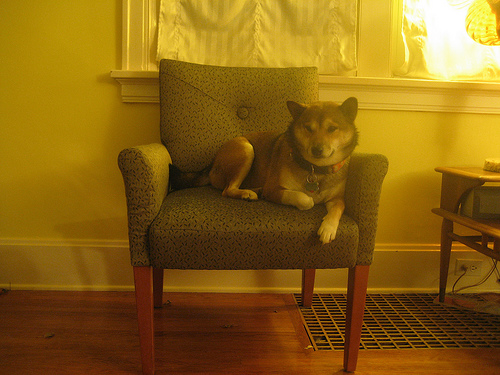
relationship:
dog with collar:
[210, 96, 360, 245] [290, 143, 350, 193]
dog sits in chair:
[199, 91, 363, 245] [118, 57, 394, 372]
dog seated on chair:
[210, 96, 360, 245] [118, 57, 394, 372]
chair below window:
[118, 57, 394, 372] [151, 1, 361, 81]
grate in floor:
[291, 293, 500, 353] [7, 286, 497, 372]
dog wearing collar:
[210, 96, 360, 245] [283, 127, 355, 177]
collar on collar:
[289, 144, 345, 193] [283, 127, 355, 177]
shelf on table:
[429, 198, 498, 248] [426, 157, 497, 323]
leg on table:
[433, 219, 457, 301] [426, 157, 497, 323]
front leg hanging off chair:
[317, 216, 341, 247] [118, 57, 394, 372]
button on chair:
[230, 98, 255, 119] [118, 57, 394, 372]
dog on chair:
[210, 96, 360, 245] [118, 57, 394, 372]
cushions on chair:
[141, 179, 372, 289] [118, 57, 394, 372]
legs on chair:
[126, 267, 162, 373] [118, 57, 394, 372]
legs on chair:
[301, 266, 317, 313] [118, 57, 394, 372]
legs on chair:
[339, 260, 372, 372] [118, 57, 394, 372]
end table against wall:
[430, 166, 500, 303] [0, 1, 500, 294]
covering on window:
[153, 0, 356, 76] [145, 4, 360, 77]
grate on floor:
[291, 293, 500, 353] [7, 286, 497, 372]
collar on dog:
[285, 140, 355, 176] [210, 96, 360, 245]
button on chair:
[237, 107, 248, 119] [118, 57, 394, 372]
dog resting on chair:
[210, 96, 360, 245] [118, 57, 394, 372]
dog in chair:
[210, 96, 360, 245] [118, 57, 394, 372]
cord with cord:
[455, 258, 482, 276] [454, 257, 484, 291]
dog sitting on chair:
[210, 96, 360, 245] [118, 57, 394, 372]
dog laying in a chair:
[210, 96, 360, 245] [118, 57, 394, 372]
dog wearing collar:
[199, 91, 363, 245] [282, 124, 350, 174]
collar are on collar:
[289, 144, 345, 193] [282, 118, 352, 178]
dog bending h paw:
[210, 96, 360, 245] [292, 184, 320, 216]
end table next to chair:
[430, 166, 500, 303] [118, 57, 394, 372]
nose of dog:
[304, 144, 324, 158] [177, 93, 366, 254]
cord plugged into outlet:
[446, 256, 489, 297] [448, 254, 477, 295]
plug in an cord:
[455, 260, 469, 278] [455, 258, 482, 276]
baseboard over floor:
[2, 238, 498, 294] [0, 292, 499, 370]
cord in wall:
[455, 258, 482, 276] [0, 1, 500, 294]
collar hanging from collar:
[289, 144, 345, 193] [286, 147, 351, 187]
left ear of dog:
[335, 96, 362, 117] [199, 91, 363, 245]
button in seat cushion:
[237, 107, 248, 119] [155, 54, 316, 190]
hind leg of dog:
[202, 129, 271, 219] [210, 96, 360, 245]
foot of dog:
[219, 184, 264, 211] [210, 96, 360, 245]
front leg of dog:
[315, 200, 347, 243] [181, 82, 368, 249]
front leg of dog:
[317, 216, 341, 247] [181, 82, 368, 249]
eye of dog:
[324, 124, 340, 136] [210, 96, 360, 245]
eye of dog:
[297, 122, 318, 138] [210, 96, 360, 245]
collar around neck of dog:
[289, 144, 345, 193] [199, 91, 363, 245]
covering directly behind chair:
[157, 7, 364, 76] [124, 62, 371, 371]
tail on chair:
[167, 159, 215, 186] [118, 57, 394, 372]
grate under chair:
[291, 293, 500, 353] [118, 57, 394, 372]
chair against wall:
[118, 57, 394, 372] [0, 2, 498, 372]